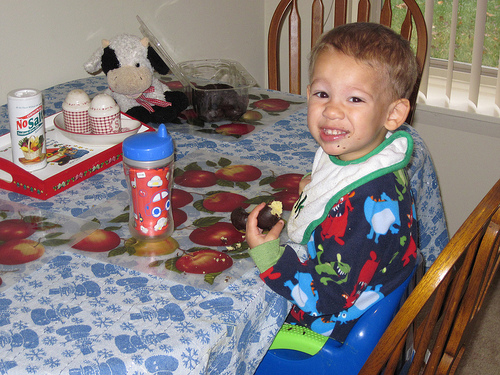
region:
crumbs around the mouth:
[322, 115, 364, 155]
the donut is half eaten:
[257, 205, 290, 237]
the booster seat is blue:
[282, 302, 372, 366]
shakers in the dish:
[65, 93, 115, 133]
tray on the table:
[1, 120, 153, 200]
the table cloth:
[99, 305, 163, 363]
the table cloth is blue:
[77, 300, 144, 360]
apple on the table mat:
[198, 244, 223, 268]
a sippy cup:
[122, 127, 183, 242]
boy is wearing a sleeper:
[317, 224, 365, 290]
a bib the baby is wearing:
[311, 171, 343, 201]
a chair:
[263, 15, 309, 91]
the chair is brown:
[266, 27, 298, 94]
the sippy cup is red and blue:
[123, 144, 177, 237]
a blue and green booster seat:
[264, 256, 428, 373]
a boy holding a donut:
[251, 33, 424, 240]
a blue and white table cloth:
[0, 295, 215, 372]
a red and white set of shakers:
[50, 96, 135, 143]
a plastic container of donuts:
[181, 40, 253, 123]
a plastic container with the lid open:
[134, 15, 268, 127]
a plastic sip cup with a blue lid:
[123, 116, 183, 241]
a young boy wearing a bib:
[283, 120, 410, 250]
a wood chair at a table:
[268, 7, 438, 114]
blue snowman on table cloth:
[66, 354, 133, 372]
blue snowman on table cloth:
[112, 325, 167, 355]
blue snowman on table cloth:
[56, 320, 103, 357]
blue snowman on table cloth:
[0, 325, 39, 352]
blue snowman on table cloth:
[30, 303, 81, 328]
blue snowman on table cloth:
[46, 280, 103, 301]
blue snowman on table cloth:
[91, 260, 123, 280]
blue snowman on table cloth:
[41, 255, 78, 280]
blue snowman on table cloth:
[240, 151, 283, 164]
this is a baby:
[247, 21, 460, 374]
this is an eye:
[344, 91, 366, 104]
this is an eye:
[314, 89, 333, 101]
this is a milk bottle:
[118, 119, 183, 244]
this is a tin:
[139, 11, 259, 125]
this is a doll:
[89, 30, 186, 138]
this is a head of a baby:
[303, 19, 417, 165]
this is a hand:
[243, 172, 397, 312]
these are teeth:
[317, 124, 349, 144]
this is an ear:
[375, 99, 408, 130]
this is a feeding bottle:
[120, 119, 170, 248]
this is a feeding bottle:
[88, 93, 124, 137]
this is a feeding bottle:
[67, 87, 93, 133]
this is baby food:
[16, 92, 45, 162]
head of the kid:
[271, 8, 438, 175]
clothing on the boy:
[197, 165, 426, 347]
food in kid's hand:
[221, 179, 316, 260]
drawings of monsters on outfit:
[245, 167, 441, 340]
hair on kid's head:
[287, 18, 429, 93]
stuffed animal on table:
[60, 23, 195, 127]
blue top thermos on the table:
[126, 118, 176, 160]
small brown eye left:
[346, 89, 366, 106]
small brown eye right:
[311, 88, 328, 102]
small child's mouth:
[321, 123, 347, 142]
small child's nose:
[321, 103, 341, 119]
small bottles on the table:
[63, 91, 117, 131]